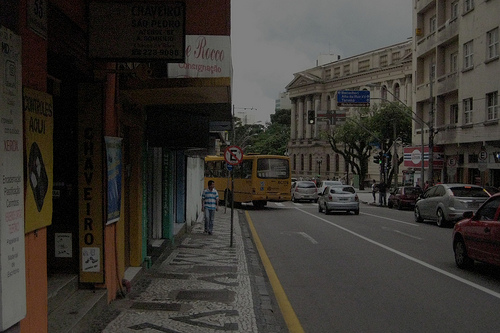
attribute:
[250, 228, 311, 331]
line — side, yellow, present, here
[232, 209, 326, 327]
lines — here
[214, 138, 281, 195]
sign — displayed, white, parking, attached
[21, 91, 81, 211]
advertisement — yellow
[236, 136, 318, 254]
bus — turning, yellow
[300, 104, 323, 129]
light — green, distant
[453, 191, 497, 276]
car — red, driving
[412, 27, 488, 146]
buidling — stone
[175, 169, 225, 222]
man — walking, wearing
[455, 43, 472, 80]
window — rectangular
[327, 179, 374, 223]
car — silver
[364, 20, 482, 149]
building — large, multi story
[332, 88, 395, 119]
sign — blue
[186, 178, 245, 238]
shirt — blue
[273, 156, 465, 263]
cars — driving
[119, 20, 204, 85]
lettering — black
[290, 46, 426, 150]
buildings — tan